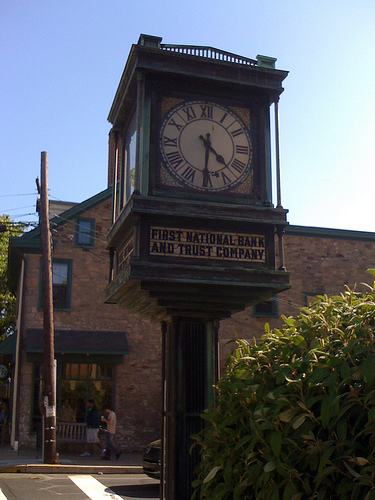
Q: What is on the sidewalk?
A: The black clock tower pole.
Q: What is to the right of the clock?
A: Green bush with leaves.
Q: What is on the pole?
A: Face of the clock.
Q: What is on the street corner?
A: Telephone and power pole.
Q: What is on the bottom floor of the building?
A: Large window.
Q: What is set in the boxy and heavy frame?
A: Elevated clock and lettering.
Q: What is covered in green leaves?
A: The curved bush.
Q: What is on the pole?
A: Clock.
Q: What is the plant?
A: Bush.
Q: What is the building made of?
A: Brick.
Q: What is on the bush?
A: Leaves.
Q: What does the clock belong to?
A: Bank.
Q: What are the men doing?
A: Walking.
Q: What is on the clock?
A: Hands.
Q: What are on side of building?
A: Windows.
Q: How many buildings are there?
A: 1.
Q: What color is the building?
A: Brown.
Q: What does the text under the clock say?
A: First National Bank and Trust Company.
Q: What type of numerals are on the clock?
A: Roman.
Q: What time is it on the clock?
A: 5:30.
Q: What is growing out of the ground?
A: A bush.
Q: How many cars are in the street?
A: 0.